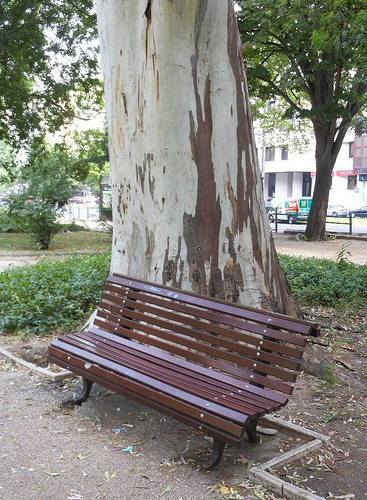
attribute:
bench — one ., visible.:
[28, 268, 315, 370]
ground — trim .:
[1, 212, 364, 496]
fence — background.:
[270, 209, 352, 234]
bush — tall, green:
[10, 136, 90, 252]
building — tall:
[43, 113, 118, 232]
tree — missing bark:
[84, 4, 303, 324]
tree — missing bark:
[246, 6, 363, 252]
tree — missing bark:
[4, 6, 104, 234]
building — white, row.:
[249, 71, 363, 227]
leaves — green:
[40, 268, 66, 287]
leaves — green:
[313, 260, 341, 283]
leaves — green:
[37, 171, 58, 199]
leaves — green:
[313, 27, 339, 58]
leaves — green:
[21, 35, 45, 68]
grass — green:
[4, 243, 119, 344]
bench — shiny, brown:
[46, 272, 318, 467]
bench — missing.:
[46, 270, 321, 441]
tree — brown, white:
[231, 11, 366, 228]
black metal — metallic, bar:
[63, 375, 95, 404]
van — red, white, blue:
[267, 195, 311, 222]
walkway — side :
[3, 335, 265, 497]